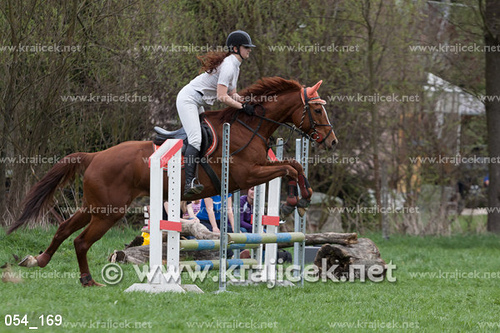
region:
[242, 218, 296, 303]
aprt of a pole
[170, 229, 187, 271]
part f a post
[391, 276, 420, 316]
part fo a grass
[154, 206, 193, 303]
part f a post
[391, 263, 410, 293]
part of a grass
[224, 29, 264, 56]
girl has black helmet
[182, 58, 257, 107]
girl has white shirt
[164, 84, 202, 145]
girl has white pants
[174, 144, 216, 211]
girl has black boots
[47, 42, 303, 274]
girl on brown horse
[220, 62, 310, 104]
horse has brown mane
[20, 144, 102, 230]
horse has brown tail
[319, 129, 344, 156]
horse has black nose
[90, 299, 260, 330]
green grass under horse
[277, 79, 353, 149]
head of a horse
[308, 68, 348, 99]
ear of a horse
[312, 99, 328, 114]
eye of a horse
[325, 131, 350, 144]
nose of a horse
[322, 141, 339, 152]
mouth of a horse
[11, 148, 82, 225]
tail of a horse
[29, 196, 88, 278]
leg of a horse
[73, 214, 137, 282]
leg of a horse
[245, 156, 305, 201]
leg of a horse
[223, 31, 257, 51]
Black and grey riders helmet.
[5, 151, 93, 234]
A brown horse tail.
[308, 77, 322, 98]
Orange ear cover on a horse.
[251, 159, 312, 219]
Two front brown legs of a horse.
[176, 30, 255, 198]
A brown haired girl in black boots.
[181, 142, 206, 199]
A girls right boot.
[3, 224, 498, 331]
A green grassy area.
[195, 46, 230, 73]
Brown curly hair on a girl.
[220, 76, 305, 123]
A brown horse mane.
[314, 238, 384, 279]
A large log on the ground.